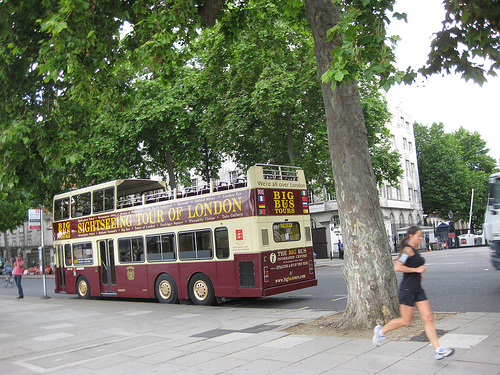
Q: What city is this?
A: London.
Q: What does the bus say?
A: Sightseeing tour of London.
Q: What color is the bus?
A: Yellow and maroon.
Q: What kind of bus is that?
A: Double Decker.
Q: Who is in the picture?
A: A woman.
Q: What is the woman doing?
A: Running.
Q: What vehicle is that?
A: Bus.